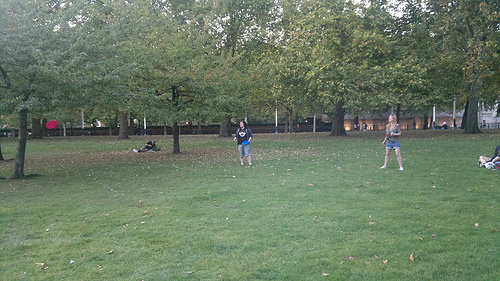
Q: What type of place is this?
A: It is a park.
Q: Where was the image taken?
A: It was taken at the park.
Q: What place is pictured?
A: It is a park.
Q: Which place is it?
A: It is a park.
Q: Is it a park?
A: Yes, it is a park.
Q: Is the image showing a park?
A: Yes, it is showing a park.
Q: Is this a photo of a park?
A: Yes, it is showing a park.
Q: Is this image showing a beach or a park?
A: It is showing a park.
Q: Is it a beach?
A: No, it is a park.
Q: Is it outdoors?
A: Yes, it is outdoors.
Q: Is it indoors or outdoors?
A: It is outdoors.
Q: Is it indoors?
A: No, it is outdoors.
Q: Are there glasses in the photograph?
A: No, there are no glasses.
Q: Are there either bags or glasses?
A: No, there are no glasses or bags.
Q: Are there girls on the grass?
A: Yes, there is a girl on the grass.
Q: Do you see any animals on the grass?
A: No, there is a girl on the grass.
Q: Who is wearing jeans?
A: The girl is wearing jeans.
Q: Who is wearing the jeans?
A: The girl is wearing jeans.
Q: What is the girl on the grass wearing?
A: The girl is wearing jeans.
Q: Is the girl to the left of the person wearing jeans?
A: Yes, the girl is wearing jeans.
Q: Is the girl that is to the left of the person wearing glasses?
A: No, the girl is wearing jeans.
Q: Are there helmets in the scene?
A: No, there are no helmets.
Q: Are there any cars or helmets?
A: No, there are no helmets or cars.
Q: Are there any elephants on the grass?
A: No, there is a person on the grass.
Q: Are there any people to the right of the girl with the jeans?
A: Yes, there is a person to the right of the girl.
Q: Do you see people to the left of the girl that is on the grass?
A: No, the person is to the right of the girl.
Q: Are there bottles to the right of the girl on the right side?
A: No, there is a person to the right of the girl.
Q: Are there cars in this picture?
A: No, there are no cars.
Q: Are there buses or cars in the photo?
A: No, there are no cars or buses.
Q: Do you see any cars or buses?
A: No, there are no cars or buses.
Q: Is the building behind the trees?
A: Yes, the building is behind the trees.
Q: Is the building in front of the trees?
A: No, the building is behind the trees.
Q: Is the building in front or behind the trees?
A: The building is behind the trees.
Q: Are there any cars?
A: No, there are no cars.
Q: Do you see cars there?
A: No, there are no cars.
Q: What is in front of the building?
A: The trees are in front of the building.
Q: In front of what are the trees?
A: The trees are in front of the building.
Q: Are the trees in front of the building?
A: Yes, the trees are in front of the building.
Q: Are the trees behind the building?
A: No, the trees are in front of the building.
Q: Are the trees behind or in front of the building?
A: The trees are in front of the building.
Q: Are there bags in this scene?
A: No, there are no bags.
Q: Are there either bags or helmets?
A: No, there are no bags or helmets.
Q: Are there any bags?
A: No, there are no bags.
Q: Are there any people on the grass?
A: Yes, there are people on the grass.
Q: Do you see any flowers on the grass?
A: No, there are people on the grass.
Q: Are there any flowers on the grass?
A: No, there are people on the grass.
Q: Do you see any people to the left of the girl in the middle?
A: Yes, there are people to the left of the girl.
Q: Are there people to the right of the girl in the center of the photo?
A: No, the people are to the left of the girl.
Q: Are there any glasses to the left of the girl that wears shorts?
A: No, there are people to the left of the girl.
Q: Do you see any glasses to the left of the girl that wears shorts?
A: No, there are people to the left of the girl.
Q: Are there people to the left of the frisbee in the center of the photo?
A: Yes, there are people to the left of the frisbee.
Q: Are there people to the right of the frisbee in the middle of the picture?
A: No, the people are to the left of the frisbee.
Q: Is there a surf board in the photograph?
A: No, there are no surfboards.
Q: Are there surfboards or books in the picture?
A: No, there are no surfboards or books.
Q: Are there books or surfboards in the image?
A: No, there are no surfboards or books.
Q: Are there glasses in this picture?
A: No, there are no glasses.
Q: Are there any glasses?
A: No, there are no glasses.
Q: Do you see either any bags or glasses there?
A: No, there are no glasses or bags.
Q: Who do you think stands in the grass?
A: The girl stands in the grass.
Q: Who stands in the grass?
A: The girl stands in the grass.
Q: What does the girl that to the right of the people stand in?
A: The girl stands in the grass.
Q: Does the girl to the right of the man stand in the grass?
A: Yes, the girl stands in the grass.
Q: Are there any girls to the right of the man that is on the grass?
A: Yes, there is a girl to the right of the man.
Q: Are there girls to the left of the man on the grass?
A: No, the girl is to the right of the man.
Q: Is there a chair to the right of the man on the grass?
A: No, there is a girl to the right of the man.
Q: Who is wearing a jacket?
A: The girl is wearing a jacket.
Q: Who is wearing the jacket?
A: The girl is wearing a jacket.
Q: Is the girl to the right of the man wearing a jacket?
A: Yes, the girl is wearing a jacket.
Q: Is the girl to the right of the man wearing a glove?
A: No, the girl is wearing a jacket.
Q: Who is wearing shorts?
A: The girl is wearing shorts.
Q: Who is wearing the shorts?
A: The girl is wearing shorts.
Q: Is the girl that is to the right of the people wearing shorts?
A: Yes, the girl is wearing shorts.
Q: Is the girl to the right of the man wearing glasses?
A: No, the girl is wearing shorts.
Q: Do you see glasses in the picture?
A: No, there are no glasses.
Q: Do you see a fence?
A: Yes, there is a fence.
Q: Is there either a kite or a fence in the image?
A: Yes, there is a fence.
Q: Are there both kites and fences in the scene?
A: No, there is a fence but no kites.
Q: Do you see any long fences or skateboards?
A: Yes, there is a long fence.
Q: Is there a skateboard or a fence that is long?
A: Yes, the fence is long.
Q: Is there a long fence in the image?
A: Yes, there is a long fence.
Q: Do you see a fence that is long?
A: Yes, there is a fence that is long.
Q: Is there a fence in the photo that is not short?
A: Yes, there is a long fence.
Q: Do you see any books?
A: No, there are no books.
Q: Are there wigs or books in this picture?
A: No, there are no books or wigs.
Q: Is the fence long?
A: Yes, the fence is long.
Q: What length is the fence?
A: The fence is long.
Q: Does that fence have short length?
A: No, the fence is long.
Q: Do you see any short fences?
A: No, there is a fence but it is long.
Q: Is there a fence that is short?
A: No, there is a fence but it is long.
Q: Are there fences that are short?
A: No, there is a fence but it is long.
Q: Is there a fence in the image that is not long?
A: No, there is a fence but it is long.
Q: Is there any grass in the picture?
A: Yes, there is grass.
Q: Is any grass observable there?
A: Yes, there is grass.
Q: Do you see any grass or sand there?
A: Yes, there is grass.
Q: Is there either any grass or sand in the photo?
A: Yes, there is grass.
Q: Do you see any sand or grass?
A: Yes, there is grass.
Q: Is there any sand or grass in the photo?
A: Yes, there is grass.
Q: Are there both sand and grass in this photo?
A: No, there is grass but no sand.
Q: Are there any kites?
A: No, there are no kites.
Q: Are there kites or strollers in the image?
A: No, there are no kites or strollers.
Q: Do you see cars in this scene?
A: No, there are no cars.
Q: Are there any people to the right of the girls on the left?
A: Yes, there are people to the right of the girls.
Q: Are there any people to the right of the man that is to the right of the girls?
A: Yes, there are people to the right of the man.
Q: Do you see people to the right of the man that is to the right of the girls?
A: Yes, there are people to the right of the man.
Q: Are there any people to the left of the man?
A: No, the people are to the right of the man.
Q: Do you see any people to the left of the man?
A: No, the people are to the right of the man.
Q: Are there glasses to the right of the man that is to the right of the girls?
A: No, there are people to the right of the man.